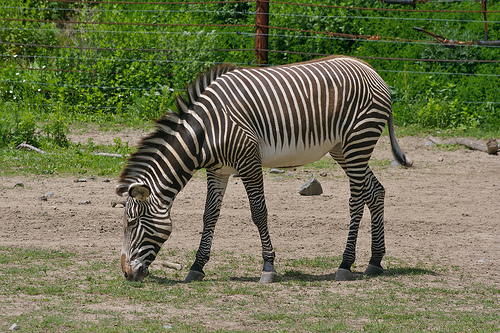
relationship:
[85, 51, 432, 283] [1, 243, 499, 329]
zebra eating grass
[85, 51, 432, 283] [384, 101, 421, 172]
zebra has tail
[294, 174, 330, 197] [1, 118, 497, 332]
rock on ground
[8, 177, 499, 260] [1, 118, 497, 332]
dirt on ground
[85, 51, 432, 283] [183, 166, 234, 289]
zebra has a leg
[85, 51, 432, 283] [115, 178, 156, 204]
zebra has an ear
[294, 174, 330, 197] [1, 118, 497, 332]
rock laying on ground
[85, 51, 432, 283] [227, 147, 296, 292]
zebra has a left front leg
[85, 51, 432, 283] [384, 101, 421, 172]
zebra has a tail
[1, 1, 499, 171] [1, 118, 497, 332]
fence surrounding ground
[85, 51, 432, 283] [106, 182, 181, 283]
zebra has a head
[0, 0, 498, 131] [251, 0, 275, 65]
fence has a metal post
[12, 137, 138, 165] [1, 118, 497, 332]
branch dead on ground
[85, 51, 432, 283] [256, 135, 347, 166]
zebra has a stomach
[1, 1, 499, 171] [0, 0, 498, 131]
bush behind fence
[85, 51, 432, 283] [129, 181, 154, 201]
zebra has left ear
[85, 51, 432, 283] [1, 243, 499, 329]
zebra eats grass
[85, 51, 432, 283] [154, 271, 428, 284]
zebra has a shadow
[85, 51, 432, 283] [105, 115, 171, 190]
zebra has neck hair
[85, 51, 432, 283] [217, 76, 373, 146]
zebra has stripes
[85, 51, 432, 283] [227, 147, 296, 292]
zebra has left front leg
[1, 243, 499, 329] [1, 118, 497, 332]
grass on ground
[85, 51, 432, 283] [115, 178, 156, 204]
zebra has ear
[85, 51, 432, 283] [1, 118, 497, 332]
zebra on ground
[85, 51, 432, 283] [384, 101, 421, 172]
zebra swinging tail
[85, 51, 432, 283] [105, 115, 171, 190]
zebra has black and white neck hair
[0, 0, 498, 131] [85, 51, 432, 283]
fence behind zebra